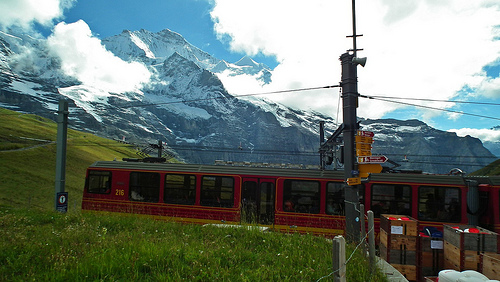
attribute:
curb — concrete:
[354, 235, 423, 280]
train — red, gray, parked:
[87, 145, 486, 266]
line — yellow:
[87, 192, 258, 221]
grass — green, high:
[16, 207, 263, 278]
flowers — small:
[236, 221, 324, 267]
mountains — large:
[20, 11, 495, 182]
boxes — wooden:
[370, 194, 492, 281]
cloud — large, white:
[206, 0, 498, 99]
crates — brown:
[384, 210, 499, 280]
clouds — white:
[33, 14, 160, 77]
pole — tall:
[332, 39, 403, 250]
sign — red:
[356, 144, 402, 172]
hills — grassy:
[15, 97, 121, 203]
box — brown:
[384, 188, 428, 282]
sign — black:
[49, 177, 89, 234]